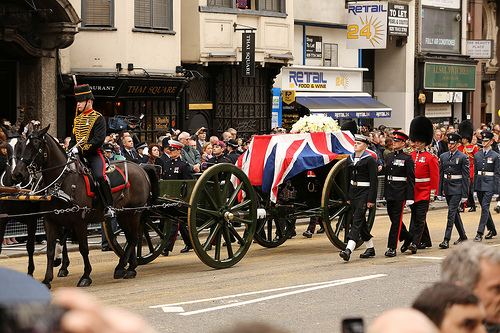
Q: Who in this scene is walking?
A: The man is walking.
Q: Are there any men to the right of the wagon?
A: Yes, there is a man to the right of the wagon.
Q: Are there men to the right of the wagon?
A: Yes, there is a man to the right of the wagon.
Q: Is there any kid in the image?
A: No, there are no children.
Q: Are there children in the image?
A: No, there are no children.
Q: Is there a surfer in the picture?
A: No, there are no surfers.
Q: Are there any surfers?
A: No, there are no surfers.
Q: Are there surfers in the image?
A: No, there are no surfers.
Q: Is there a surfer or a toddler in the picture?
A: No, there are no surfers or toddlers.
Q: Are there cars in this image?
A: No, there are no cars.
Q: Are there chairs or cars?
A: No, there are no cars or chairs.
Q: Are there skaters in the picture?
A: No, there are no skaters.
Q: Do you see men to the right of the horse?
A: Yes, there is a man to the right of the horse.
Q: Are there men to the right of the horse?
A: Yes, there is a man to the right of the horse.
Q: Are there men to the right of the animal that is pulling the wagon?
A: Yes, there is a man to the right of the horse.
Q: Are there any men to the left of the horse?
A: No, the man is to the right of the horse.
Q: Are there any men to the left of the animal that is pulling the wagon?
A: No, the man is to the right of the horse.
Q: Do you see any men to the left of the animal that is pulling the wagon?
A: No, the man is to the right of the horse.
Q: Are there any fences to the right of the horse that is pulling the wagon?
A: No, there is a man to the right of the horse.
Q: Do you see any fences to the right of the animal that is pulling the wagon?
A: No, there is a man to the right of the horse.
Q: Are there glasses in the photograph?
A: No, there are no glasses.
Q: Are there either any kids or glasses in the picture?
A: No, there are no glasses or kids.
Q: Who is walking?
A: The man is walking.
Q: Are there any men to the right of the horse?
A: Yes, there is a man to the right of the horse.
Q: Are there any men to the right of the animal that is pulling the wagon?
A: Yes, there is a man to the right of the horse.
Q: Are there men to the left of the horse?
A: No, the man is to the right of the horse.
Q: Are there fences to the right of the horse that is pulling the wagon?
A: No, there is a man to the right of the horse.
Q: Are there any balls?
A: No, there are no balls.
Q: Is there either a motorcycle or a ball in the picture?
A: No, there are no balls or motorcycles.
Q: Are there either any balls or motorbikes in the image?
A: No, there are no balls or motorbikes.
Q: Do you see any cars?
A: No, there are no cars.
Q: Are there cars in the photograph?
A: No, there are no cars.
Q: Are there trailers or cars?
A: No, there are no cars or trailers.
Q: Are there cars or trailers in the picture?
A: No, there are no cars or trailers.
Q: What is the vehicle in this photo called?
A: The vehicle is a wagon.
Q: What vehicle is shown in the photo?
A: The vehicle is a wagon.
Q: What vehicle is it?
A: The vehicle is a wagon.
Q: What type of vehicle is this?
A: This is a wagon.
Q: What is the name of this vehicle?
A: This is a wagon.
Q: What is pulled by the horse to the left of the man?
A: The wagon is pulled by the horse.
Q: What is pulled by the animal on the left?
A: The wagon is pulled by the horse.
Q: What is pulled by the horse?
A: The wagon is pulled by the horse.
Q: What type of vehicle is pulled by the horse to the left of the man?
A: The vehicle is a wagon.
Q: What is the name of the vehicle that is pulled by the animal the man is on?
A: The vehicle is a wagon.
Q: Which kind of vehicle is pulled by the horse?
A: The vehicle is a wagon.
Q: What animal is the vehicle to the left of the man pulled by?
A: The wagon is pulled by the horse.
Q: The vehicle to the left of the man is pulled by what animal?
A: The wagon is pulled by the horse.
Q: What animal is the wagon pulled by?
A: The wagon is pulled by the horse.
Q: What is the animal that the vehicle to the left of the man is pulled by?
A: The animal is a horse.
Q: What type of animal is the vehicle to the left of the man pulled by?
A: The wagon is pulled by the horse.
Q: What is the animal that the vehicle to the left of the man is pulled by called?
A: The animal is a horse.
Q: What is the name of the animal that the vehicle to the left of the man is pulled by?
A: The animal is a horse.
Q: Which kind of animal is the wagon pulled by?
A: The wagon is pulled by the horse.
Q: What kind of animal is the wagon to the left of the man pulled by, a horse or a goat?
A: The wagon is pulled by a horse.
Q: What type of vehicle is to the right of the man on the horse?
A: The vehicle is a wagon.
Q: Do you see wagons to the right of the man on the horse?
A: Yes, there is a wagon to the right of the man.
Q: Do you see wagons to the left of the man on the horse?
A: No, the wagon is to the right of the man.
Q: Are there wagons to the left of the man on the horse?
A: No, the wagon is to the right of the man.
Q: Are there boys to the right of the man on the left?
A: No, there is a wagon to the right of the man.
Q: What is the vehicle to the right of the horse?
A: The vehicle is a wagon.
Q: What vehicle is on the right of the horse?
A: The vehicle is a wagon.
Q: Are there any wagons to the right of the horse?
A: Yes, there is a wagon to the right of the horse.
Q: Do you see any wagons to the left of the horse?
A: No, the wagon is to the right of the horse.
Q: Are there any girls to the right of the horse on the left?
A: No, there is a wagon to the right of the horse.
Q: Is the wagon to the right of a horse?
A: Yes, the wagon is to the right of a horse.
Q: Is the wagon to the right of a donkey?
A: No, the wagon is to the right of a horse.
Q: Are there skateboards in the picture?
A: No, there are no skateboards.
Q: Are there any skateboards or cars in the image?
A: No, there are no skateboards or cars.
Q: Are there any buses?
A: No, there are no buses.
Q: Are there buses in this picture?
A: No, there are no buses.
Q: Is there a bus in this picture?
A: No, there are no buses.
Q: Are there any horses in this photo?
A: Yes, there is a horse.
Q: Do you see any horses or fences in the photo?
A: Yes, there is a horse.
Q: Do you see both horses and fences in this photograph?
A: No, there is a horse but no fences.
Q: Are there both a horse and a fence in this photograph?
A: No, there is a horse but no fences.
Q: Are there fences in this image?
A: No, there are no fences.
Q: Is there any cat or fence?
A: No, there are no fences or cats.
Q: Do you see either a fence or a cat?
A: No, there are no fences or cats.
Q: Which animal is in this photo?
A: The animal is a horse.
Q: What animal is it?
A: The animal is a horse.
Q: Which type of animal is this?
A: This is a horse.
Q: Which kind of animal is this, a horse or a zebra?
A: This is a horse.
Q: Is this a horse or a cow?
A: This is a horse.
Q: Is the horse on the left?
A: Yes, the horse is on the left of the image.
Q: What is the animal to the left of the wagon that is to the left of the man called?
A: The animal is a horse.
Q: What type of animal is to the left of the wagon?
A: The animal is a horse.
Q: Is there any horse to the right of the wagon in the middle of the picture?
A: No, the horse is to the left of the wagon.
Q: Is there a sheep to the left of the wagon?
A: No, there is a horse to the left of the wagon.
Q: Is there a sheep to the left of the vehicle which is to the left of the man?
A: No, there is a horse to the left of the wagon.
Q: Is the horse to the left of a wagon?
A: Yes, the horse is to the left of a wagon.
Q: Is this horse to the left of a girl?
A: No, the horse is to the left of a wagon.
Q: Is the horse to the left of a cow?
A: No, the horse is to the left of a man.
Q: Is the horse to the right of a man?
A: No, the horse is to the left of a man.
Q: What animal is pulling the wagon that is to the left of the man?
A: The horse is pulling the wagon.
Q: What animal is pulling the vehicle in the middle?
A: The horse is pulling the wagon.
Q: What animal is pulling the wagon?
A: The horse is pulling the wagon.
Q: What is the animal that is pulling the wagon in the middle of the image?
A: The animal is a horse.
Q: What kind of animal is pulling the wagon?
A: The animal is a horse.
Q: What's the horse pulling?
A: The horse is pulling the wagon.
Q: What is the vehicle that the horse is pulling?
A: The vehicle is a wagon.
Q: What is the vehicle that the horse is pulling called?
A: The vehicle is a wagon.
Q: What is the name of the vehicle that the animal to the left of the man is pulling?
A: The vehicle is a wagon.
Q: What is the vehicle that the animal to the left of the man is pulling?
A: The vehicle is a wagon.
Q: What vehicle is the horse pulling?
A: The horse is pulling the wagon.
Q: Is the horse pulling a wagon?
A: Yes, the horse is pulling a wagon.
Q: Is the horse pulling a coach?
A: No, the horse is pulling a wagon.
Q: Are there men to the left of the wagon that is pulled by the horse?
A: Yes, there is a man to the left of the wagon.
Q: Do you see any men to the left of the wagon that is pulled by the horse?
A: Yes, there is a man to the left of the wagon.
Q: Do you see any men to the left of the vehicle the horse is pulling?
A: Yes, there is a man to the left of the wagon.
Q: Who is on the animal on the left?
A: The man is on the horse.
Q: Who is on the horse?
A: The man is on the horse.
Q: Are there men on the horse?
A: Yes, there is a man on the horse.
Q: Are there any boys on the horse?
A: No, there is a man on the horse.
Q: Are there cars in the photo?
A: No, there are no cars.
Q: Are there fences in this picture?
A: No, there are no fences.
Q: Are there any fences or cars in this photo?
A: No, there are no fences or cars.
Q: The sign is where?
A: The sign is on the restaurant.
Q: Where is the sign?
A: The sign is on the restaurant.